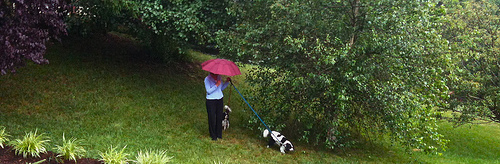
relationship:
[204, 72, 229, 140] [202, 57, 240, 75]
woman under umbrella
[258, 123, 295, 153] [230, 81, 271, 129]
dog on leash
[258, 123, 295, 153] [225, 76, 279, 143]
dog on leash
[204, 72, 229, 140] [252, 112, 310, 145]
woman walking dog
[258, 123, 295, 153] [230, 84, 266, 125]
dog on leash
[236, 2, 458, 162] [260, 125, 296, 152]
tree near dog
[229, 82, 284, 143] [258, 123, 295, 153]
leash attached to dog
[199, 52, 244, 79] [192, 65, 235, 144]
umbrella shading woman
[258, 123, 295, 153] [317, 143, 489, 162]
dog on grass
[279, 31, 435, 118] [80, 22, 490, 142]
leaves from a tree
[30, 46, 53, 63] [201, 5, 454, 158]
leaves on tree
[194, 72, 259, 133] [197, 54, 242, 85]
person holding umbrella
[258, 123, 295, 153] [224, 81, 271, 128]
dog on leash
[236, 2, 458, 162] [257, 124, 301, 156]
tree by dog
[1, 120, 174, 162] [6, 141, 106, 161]
flowers planted in dirt bed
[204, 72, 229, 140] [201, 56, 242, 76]
woman holding an umbrella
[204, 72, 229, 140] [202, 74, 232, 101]
woman wearing a blue shirt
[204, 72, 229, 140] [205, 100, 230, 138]
woman wearing a pair of black pants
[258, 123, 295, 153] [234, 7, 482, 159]
dog standing next to bush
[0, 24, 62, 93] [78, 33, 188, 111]
flowers in shade